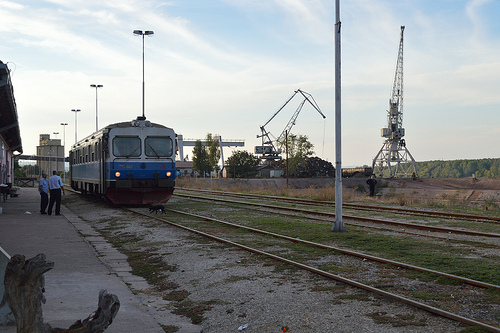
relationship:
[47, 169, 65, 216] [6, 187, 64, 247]
men standing on sidewalk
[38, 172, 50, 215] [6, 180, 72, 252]
men standing on sidewalk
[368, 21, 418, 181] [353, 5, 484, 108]
crane in sky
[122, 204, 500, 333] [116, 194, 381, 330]
railroad tracks on ground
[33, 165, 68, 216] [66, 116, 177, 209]
men standing by train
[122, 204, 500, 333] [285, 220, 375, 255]
railroad tracks covered with moss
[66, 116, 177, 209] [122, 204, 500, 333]
train stopped on railroad tracks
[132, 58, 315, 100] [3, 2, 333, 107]
clouds in sky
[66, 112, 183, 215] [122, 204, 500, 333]
train on railroad tracks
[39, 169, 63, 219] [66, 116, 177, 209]
men standing near train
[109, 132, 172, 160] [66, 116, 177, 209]
windows at front train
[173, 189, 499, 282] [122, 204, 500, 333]
grass growing between railroad tracks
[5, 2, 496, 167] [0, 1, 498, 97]
sky filled with cloud